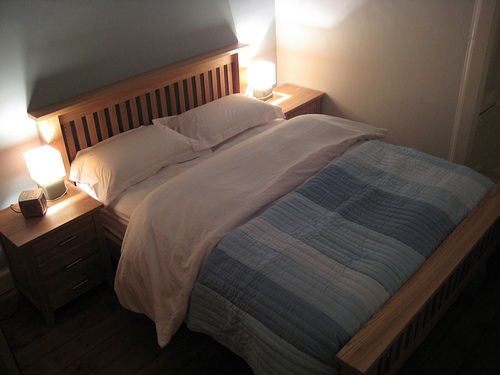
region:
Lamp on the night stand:
[19, 131, 67, 200]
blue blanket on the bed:
[223, 221, 388, 333]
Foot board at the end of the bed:
[333, 302, 498, 369]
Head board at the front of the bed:
[18, 33, 250, 133]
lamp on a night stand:
[248, 41, 281, 102]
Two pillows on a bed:
[67, 82, 275, 192]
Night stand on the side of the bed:
[240, 56, 337, 116]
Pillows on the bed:
[154, 100, 293, 198]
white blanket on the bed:
[171, 114, 295, 214]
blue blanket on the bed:
[286, 210, 421, 275]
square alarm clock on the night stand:
[18, 187, 45, 217]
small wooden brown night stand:
[1, 180, 115, 322]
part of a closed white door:
[466, 2, 496, 175]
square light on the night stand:
[24, 145, 67, 197]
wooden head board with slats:
[26, 42, 246, 186]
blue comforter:
[183, 137, 490, 372]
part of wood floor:
[4, 277, 239, 368]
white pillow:
[157, 91, 279, 145]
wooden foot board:
[337, 182, 497, 368]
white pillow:
[68, 121, 205, 206]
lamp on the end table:
[21, 142, 67, 202]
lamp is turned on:
[25, 142, 72, 202]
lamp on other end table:
[243, 52, 279, 103]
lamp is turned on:
[244, 57, 278, 101]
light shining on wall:
[219, 2, 364, 62]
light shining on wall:
[0, 33, 67, 210]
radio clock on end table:
[14, 185, 49, 224]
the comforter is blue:
[185, 139, 496, 373]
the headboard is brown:
[23, 34, 250, 176]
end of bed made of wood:
[328, 187, 496, 371]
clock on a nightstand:
[11, 181, 48, 224]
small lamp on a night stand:
[244, 58, 280, 108]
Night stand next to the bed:
[13, 203, 117, 327]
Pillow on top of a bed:
[118, 93, 285, 202]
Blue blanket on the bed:
[241, 211, 490, 373]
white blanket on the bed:
[201, 148, 289, 203]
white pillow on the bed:
[85, 130, 177, 187]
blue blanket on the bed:
[303, 210, 389, 272]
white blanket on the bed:
[215, 157, 262, 203]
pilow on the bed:
[97, 133, 194, 190]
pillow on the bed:
[160, 73, 262, 145]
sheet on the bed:
[290, 206, 380, 297]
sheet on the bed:
[179, 163, 271, 217]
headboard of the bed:
[2, 52, 209, 135]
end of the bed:
[334, 281, 481, 355]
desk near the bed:
[19, 202, 95, 236]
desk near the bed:
[297, 86, 333, 114]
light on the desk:
[33, 150, 102, 202]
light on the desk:
[250, 74, 293, 99]